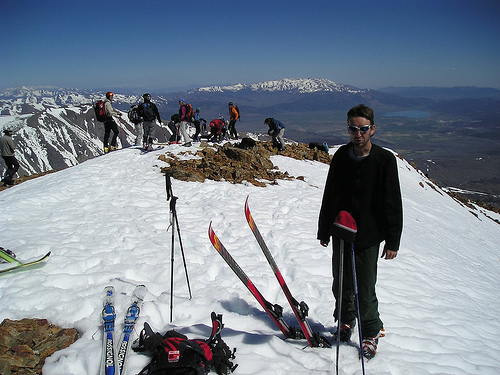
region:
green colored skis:
[0, 245, 56, 270]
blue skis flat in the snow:
[83, 284, 148, 372]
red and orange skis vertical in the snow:
[201, 196, 328, 351]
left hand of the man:
[379, 243, 405, 265]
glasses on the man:
[347, 120, 373, 136]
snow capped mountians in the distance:
[199, 74, 374, 98]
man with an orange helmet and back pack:
[88, 91, 125, 151]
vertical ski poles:
[149, 166, 204, 324]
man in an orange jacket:
[225, 98, 242, 139]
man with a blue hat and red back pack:
[176, 99, 197, 146]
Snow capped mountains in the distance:
[0, 71, 399, 186]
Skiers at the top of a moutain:
[82, 80, 297, 170]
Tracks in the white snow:
[52, 175, 159, 277]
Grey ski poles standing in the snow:
[154, 153, 201, 326]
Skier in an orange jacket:
[222, 96, 241, 137]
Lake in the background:
[379, 104, 434, 125]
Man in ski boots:
[308, 99, 410, 365]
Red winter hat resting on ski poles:
[324, 204, 369, 246]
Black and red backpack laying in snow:
[130, 311, 238, 373]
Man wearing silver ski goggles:
[345, 121, 374, 138]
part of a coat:
[376, 198, 392, 214]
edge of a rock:
[234, 157, 251, 180]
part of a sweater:
[363, 195, 389, 214]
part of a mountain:
[61, 139, 81, 163]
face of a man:
[353, 125, 370, 146]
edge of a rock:
[236, 158, 250, 202]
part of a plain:
[452, 110, 469, 129]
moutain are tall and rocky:
[0, 65, 498, 373]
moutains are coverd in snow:
[0, 80, 498, 373]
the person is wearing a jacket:
[307, 146, 407, 250]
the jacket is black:
[308, 145, 421, 253]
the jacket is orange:
[226, 108, 241, 125]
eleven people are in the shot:
[0, 88, 407, 360]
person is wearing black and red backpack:
[88, 90, 124, 157]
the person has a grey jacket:
[103, 96, 119, 118]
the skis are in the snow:
[163, 174, 198, 325]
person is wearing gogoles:
[349, 123, 372, 134]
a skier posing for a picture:
[225, 93, 400, 373]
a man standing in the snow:
[204, 80, 430, 367]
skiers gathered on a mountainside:
[72, 79, 300, 166]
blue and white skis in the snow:
[70, 249, 139, 373]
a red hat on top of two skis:
[331, 208, 362, 265]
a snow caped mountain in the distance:
[191, 65, 366, 115]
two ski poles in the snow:
[150, 166, 196, 328]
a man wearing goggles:
[332, 98, 373, 160]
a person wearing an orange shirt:
[217, 97, 247, 148]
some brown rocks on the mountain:
[150, 135, 293, 186]